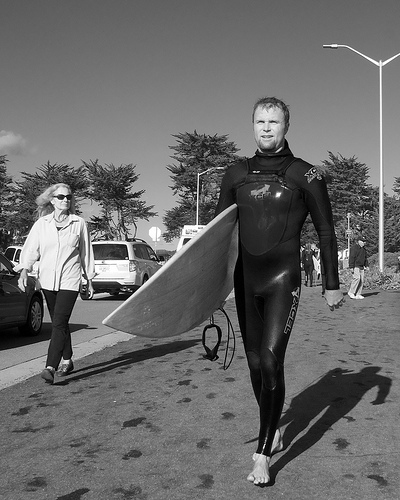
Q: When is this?
A: Daytime.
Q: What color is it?
A: Black.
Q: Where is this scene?
A: Beside a beach-side road.